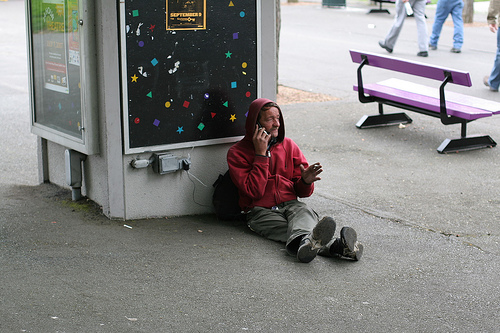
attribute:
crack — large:
[343, 192, 483, 255]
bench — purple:
[348, 50, 498, 151]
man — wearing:
[244, 94, 366, 258]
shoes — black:
[295, 212, 365, 264]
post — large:
[110, 1, 266, 158]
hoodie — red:
[224, 97, 316, 211]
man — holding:
[217, 75, 353, 219]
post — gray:
[64, 147, 83, 205]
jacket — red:
[229, 137, 314, 207]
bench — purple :
[348, 42, 498, 158]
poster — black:
[122, 1, 262, 154]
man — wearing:
[199, 93, 367, 273]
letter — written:
[186, 6, 198, 18]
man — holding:
[217, 90, 376, 277]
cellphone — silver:
[258, 125, 267, 140]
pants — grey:
[239, 197, 339, 252]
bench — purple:
[344, 47, 486, 142]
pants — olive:
[259, 204, 364, 270]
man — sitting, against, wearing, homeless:
[223, 93, 366, 266]